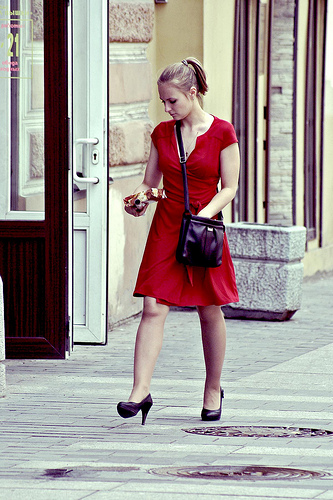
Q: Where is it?
A: This is at the sidewalk.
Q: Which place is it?
A: It is a sidewalk.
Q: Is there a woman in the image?
A: Yes, there is a woman.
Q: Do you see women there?
A: Yes, there is a woman.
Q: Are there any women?
A: Yes, there is a woman.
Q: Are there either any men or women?
A: Yes, there is a woman.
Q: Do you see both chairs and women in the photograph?
A: No, there is a woman but no chairs.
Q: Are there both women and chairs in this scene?
A: No, there is a woman but no chairs.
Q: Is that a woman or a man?
A: That is a woman.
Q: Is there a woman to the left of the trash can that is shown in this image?
A: Yes, there is a woman to the left of the trash can.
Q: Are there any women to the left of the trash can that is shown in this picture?
A: Yes, there is a woman to the left of the trash can.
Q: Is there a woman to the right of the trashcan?
A: No, the woman is to the left of the trashcan.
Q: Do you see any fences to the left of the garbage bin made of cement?
A: No, there is a woman to the left of the trash can.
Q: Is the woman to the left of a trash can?
A: Yes, the woman is to the left of a trash can.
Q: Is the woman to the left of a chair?
A: No, the woman is to the left of a trash can.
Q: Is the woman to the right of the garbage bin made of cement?
A: No, the woman is to the left of the garbage can.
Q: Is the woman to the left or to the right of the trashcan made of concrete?
A: The woman is to the left of the garbage can.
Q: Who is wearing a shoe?
A: The woman is wearing a shoe.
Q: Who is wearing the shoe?
A: The woman is wearing a shoe.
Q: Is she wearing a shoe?
A: Yes, the woman is wearing a shoe.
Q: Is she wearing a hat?
A: No, the woman is wearing a shoe.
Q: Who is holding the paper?
A: The woman is holding the paper.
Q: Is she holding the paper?
A: Yes, the woman is holding the paper.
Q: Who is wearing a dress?
A: The woman is wearing a dress.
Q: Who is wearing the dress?
A: The woman is wearing a dress.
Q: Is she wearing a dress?
A: Yes, the woman is wearing a dress.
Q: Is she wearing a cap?
A: No, the woman is wearing a dress.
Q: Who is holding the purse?
A: The woman is holding the purse.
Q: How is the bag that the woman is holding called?
A: The bag is a purse.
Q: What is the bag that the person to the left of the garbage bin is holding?
A: The bag is a purse.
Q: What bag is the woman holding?
A: The woman is holding the purse.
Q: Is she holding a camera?
A: No, the woman is holding the purse.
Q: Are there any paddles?
A: No, there are no paddles.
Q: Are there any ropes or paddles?
A: No, there are no paddles or ropes.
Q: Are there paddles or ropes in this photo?
A: No, there are no paddles or ropes.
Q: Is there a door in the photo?
A: Yes, there is a door.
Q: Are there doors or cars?
A: Yes, there is a door.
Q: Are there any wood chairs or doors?
A: Yes, there is a wood door.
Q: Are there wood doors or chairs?
A: Yes, there is a wood door.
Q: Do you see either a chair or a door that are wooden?
A: Yes, the door is wooden.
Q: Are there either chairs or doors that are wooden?
A: Yes, the door is wooden.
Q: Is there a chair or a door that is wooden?
A: Yes, the door is wooden.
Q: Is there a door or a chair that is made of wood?
A: Yes, the door is made of wood.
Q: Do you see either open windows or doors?
A: Yes, there is an open door.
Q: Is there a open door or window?
A: Yes, there is an open door.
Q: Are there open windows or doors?
A: Yes, there is an open door.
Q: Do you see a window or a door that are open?
A: Yes, the door is open.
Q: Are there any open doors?
A: Yes, there is an open door.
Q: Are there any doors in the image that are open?
A: Yes, there is a door that is open.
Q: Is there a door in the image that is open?
A: Yes, there is a door that is open.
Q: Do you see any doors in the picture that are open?
A: Yes, there is a door that is open.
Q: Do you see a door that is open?
A: Yes, there is a door that is open.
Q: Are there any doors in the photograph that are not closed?
A: Yes, there is a open door.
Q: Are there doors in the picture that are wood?
A: Yes, there is a wood door.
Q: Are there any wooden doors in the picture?
A: Yes, there is a wood door.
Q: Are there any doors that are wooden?
A: Yes, there is a door that is wooden.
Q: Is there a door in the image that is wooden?
A: Yes, there is a door that is wooden.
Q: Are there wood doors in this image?
A: Yes, there is a door that is made of wood.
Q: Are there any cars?
A: No, there are no cars.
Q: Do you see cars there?
A: No, there are no cars.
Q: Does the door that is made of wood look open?
A: Yes, the door is open.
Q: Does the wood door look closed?
A: No, the door is open.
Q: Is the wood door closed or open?
A: The door is open.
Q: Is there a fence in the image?
A: No, there are no fences.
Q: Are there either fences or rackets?
A: No, there are no fences or rackets.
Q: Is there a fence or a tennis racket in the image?
A: No, there are no fences or rackets.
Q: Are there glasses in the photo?
A: No, there are no glasses.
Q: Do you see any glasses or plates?
A: No, there are no glasses or plates.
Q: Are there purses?
A: Yes, there is a purse.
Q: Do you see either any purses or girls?
A: Yes, there is a purse.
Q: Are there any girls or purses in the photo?
A: Yes, there is a purse.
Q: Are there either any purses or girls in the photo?
A: Yes, there is a purse.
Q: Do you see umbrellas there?
A: No, there are no umbrellas.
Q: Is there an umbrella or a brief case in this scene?
A: No, there are no umbrellas or briefcases.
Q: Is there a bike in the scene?
A: No, there are no bikes.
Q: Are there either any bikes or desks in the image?
A: No, there are no bikes or desks.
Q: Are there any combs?
A: No, there are no combs.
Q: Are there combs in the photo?
A: No, there are no combs.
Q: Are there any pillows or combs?
A: No, there are no combs or pillows.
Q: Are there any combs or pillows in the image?
A: No, there are no combs or pillows.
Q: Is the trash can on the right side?
A: Yes, the trash can is on the right of the image.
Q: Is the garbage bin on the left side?
A: No, the garbage bin is on the right of the image.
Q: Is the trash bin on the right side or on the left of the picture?
A: The trash bin is on the right of the image.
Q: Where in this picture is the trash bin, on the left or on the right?
A: The trash bin is on the right of the image.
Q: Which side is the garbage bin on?
A: The garbage bin is on the right of the image.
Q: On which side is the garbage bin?
A: The garbage bin is on the right of the image.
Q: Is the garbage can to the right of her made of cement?
A: Yes, the trash can is made of cement.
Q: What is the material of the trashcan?
A: The trashcan is made of cement.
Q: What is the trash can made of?
A: The trashcan is made of concrete.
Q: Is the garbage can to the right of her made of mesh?
A: No, the trash can is made of concrete.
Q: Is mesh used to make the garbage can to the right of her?
A: No, the trash can is made of concrete.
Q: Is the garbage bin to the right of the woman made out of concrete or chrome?
A: The garbage bin is made of concrete.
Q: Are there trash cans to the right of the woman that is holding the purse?
A: Yes, there is a trash can to the right of the woman.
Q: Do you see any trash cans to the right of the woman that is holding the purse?
A: Yes, there is a trash can to the right of the woman.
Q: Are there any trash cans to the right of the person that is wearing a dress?
A: Yes, there is a trash can to the right of the woman.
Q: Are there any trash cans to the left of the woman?
A: No, the trash can is to the right of the woman.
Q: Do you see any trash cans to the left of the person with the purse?
A: No, the trash can is to the right of the woman.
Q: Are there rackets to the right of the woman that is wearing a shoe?
A: No, there is a trash can to the right of the woman.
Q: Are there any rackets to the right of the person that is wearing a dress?
A: No, there is a trash can to the right of the woman.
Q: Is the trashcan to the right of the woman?
A: Yes, the trashcan is to the right of the woman.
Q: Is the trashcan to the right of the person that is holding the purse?
A: Yes, the trashcan is to the right of the woman.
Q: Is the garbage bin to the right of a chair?
A: No, the garbage bin is to the right of the woman.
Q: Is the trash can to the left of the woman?
A: No, the trash can is to the right of the woman.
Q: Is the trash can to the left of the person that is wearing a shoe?
A: No, the trash can is to the right of the woman.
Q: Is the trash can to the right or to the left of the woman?
A: The trash can is to the right of the woman.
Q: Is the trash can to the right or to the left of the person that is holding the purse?
A: The trash can is to the right of the woman.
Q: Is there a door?
A: Yes, there is a door.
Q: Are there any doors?
A: Yes, there is a door.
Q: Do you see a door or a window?
A: Yes, there is a door.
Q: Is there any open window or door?
A: Yes, there is an open door.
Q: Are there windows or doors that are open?
A: Yes, the door is open.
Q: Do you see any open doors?
A: Yes, there is an open door.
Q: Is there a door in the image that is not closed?
A: Yes, there is a open door.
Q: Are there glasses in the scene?
A: No, there are no glasses.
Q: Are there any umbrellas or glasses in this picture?
A: No, there are no glasses or umbrellas.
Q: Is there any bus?
A: No, there are no buses.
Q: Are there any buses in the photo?
A: No, there are no buses.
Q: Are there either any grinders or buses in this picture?
A: No, there are no buses or grinders.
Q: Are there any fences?
A: No, there are no fences.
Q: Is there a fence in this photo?
A: No, there are no fences.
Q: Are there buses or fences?
A: No, there are no fences or buses.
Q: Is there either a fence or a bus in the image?
A: No, there are no fences or buses.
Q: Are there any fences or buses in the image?
A: No, there are no fences or buses.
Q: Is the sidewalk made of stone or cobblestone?
A: The sidewalk is made of stone.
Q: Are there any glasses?
A: No, there are no glasses.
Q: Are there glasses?
A: No, there are no glasses.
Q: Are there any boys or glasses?
A: No, there are no glasses or boys.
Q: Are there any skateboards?
A: No, there are no skateboards.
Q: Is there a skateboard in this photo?
A: No, there are no skateboards.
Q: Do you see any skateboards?
A: No, there are no skateboards.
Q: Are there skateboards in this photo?
A: No, there are no skateboards.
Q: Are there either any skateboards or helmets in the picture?
A: No, there are no skateboards or helmets.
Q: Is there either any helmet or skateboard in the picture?
A: No, there are no skateboards or helmets.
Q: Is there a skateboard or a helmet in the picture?
A: No, there are no skateboards or helmets.